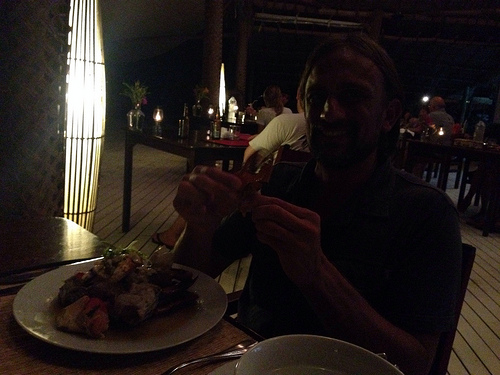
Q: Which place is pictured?
A: It is a restaurant.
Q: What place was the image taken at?
A: It was taken at the restaurant.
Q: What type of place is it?
A: It is a restaurant.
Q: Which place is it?
A: It is a restaurant.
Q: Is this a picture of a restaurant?
A: Yes, it is showing a restaurant.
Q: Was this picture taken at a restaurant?
A: Yes, it was taken in a restaurant.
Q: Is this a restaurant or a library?
A: It is a restaurant.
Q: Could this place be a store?
A: No, it is a restaurant.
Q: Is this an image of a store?
A: No, the picture is showing a restaurant.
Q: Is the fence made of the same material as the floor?
A: Yes, both the fence and the floor are made of wood.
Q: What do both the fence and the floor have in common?
A: The material, both the fence and the floor are wooden.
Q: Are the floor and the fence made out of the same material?
A: Yes, both the floor and the fence are made of wood.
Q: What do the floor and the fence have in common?
A: The material, both the floor and the fence are wooden.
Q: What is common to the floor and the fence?
A: The material, both the floor and the fence are wooden.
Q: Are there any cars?
A: No, there are no cars.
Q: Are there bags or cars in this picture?
A: No, there are no cars or bags.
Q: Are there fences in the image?
A: Yes, there is a fence.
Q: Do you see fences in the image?
A: Yes, there is a fence.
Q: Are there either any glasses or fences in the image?
A: Yes, there is a fence.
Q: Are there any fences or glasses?
A: Yes, there is a fence.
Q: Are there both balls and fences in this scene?
A: No, there is a fence but no balls.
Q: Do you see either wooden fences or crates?
A: Yes, there is a wood fence.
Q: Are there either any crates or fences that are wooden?
A: Yes, the fence is wooden.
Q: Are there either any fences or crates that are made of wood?
A: Yes, the fence is made of wood.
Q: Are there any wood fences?
A: Yes, there is a fence that is made of wood.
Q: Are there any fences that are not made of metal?
A: Yes, there is a fence that is made of wood.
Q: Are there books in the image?
A: No, there are no books.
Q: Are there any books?
A: No, there are no books.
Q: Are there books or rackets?
A: No, there are no books or rackets.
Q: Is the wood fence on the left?
A: Yes, the fence is on the left of the image.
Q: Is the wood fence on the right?
A: No, the fence is on the left of the image.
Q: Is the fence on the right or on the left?
A: The fence is on the left of the image.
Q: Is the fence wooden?
A: Yes, the fence is wooden.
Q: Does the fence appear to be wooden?
A: Yes, the fence is wooden.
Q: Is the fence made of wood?
A: Yes, the fence is made of wood.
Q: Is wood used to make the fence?
A: Yes, the fence is made of wood.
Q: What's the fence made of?
A: The fence is made of wood.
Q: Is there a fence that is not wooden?
A: No, there is a fence but it is wooden.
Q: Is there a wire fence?
A: No, there is a fence but it is made of wood.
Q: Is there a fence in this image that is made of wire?
A: No, there is a fence but it is made of wood.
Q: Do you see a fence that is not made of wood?
A: No, there is a fence but it is made of wood.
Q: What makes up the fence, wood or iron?
A: The fence is made of wood.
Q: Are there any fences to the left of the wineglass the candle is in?
A: Yes, there is a fence to the left of the wine glass.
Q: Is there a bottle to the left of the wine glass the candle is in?
A: No, there is a fence to the left of the wine glass.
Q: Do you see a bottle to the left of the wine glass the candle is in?
A: No, there is a fence to the left of the wine glass.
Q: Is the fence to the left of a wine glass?
A: Yes, the fence is to the left of a wine glass.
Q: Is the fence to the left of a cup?
A: No, the fence is to the left of a wine glass.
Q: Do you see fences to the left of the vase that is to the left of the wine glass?
A: Yes, there is a fence to the left of the vase.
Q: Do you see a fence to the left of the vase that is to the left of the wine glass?
A: Yes, there is a fence to the left of the vase.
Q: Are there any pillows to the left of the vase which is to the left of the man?
A: No, there is a fence to the left of the vase.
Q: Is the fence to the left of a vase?
A: Yes, the fence is to the left of a vase.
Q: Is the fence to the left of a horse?
A: No, the fence is to the left of a vase.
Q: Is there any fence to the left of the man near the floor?
A: Yes, there is a fence to the left of the man.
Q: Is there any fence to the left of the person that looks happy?
A: Yes, there is a fence to the left of the man.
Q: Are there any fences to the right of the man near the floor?
A: No, the fence is to the left of the man.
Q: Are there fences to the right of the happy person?
A: No, the fence is to the left of the man.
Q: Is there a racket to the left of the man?
A: No, there is a fence to the left of the man.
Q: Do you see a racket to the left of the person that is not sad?
A: No, there is a fence to the left of the man.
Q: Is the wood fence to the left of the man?
A: Yes, the fence is to the left of the man.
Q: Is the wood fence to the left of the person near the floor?
A: Yes, the fence is to the left of the man.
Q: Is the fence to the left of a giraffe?
A: No, the fence is to the left of the man.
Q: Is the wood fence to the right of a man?
A: No, the fence is to the left of a man.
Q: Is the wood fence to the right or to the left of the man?
A: The fence is to the left of the man.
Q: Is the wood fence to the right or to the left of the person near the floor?
A: The fence is to the left of the man.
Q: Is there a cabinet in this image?
A: No, there are no cabinets.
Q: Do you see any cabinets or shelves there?
A: No, there are no cabinets or shelves.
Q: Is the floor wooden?
A: Yes, the floor is wooden.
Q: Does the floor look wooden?
A: Yes, the floor is wooden.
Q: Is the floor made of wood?
A: Yes, the floor is made of wood.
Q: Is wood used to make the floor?
A: Yes, the floor is made of wood.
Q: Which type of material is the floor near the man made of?
A: The floor is made of wood.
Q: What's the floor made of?
A: The floor is made of wood.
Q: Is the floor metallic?
A: No, the floor is wooden.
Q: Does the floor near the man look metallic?
A: No, the floor is wooden.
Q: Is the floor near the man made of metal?
A: No, the floor is made of wood.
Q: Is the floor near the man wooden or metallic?
A: The floor is wooden.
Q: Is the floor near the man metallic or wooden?
A: The floor is wooden.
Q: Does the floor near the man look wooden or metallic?
A: The floor is wooden.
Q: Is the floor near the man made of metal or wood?
A: The floor is made of wood.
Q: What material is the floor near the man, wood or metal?
A: The floor is made of wood.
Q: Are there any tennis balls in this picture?
A: No, there are no tennis balls.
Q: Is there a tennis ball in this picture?
A: No, there are no tennis balls.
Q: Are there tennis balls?
A: No, there are no tennis balls.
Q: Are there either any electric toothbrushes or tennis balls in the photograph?
A: No, there are no tennis balls or electric toothbrushes.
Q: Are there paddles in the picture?
A: No, there are no paddles.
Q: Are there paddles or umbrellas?
A: No, there are no paddles or umbrellas.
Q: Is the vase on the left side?
A: Yes, the vase is on the left of the image.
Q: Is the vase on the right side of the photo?
A: No, the vase is on the left of the image.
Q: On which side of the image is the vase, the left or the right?
A: The vase is on the left of the image.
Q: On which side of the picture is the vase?
A: The vase is on the left of the image.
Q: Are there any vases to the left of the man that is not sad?
A: Yes, there is a vase to the left of the man.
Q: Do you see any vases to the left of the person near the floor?
A: Yes, there is a vase to the left of the man.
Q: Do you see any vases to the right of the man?
A: No, the vase is to the left of the man.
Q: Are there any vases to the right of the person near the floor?
A: No, the vase is to the left of the man.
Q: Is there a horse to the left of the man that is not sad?
A: No, there is a vase to the left of the man.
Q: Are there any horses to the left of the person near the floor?
A: No, there is a vase to the left of the man.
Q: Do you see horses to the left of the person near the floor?
A: No, there is a vase to the left of the man.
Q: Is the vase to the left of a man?
A: Yes, the vase is to the left of a man.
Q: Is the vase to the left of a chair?
A: No, the vase is to the left of a man.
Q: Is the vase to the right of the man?
A: No, the vase is to the left of the man.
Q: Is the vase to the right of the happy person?
A: No, the vase is to the left of the man.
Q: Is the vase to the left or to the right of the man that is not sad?
A: The vase is to the left of the man.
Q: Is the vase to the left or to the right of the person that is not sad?
A: The vase is to the left of the man.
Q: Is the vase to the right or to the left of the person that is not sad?
A: The vase is to the left of the man.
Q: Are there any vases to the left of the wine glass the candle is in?
A: Yes, there is a vase to the left of the wineglass.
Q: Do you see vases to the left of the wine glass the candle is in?
A: Yes, there is a vase to the left of the wineglass.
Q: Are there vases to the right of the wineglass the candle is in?
A: No, the vase is to the left of the wine glass.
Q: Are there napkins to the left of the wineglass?
A: No, there is a vase to the left of the wineglass.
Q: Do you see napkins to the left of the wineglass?
A: No, there is a vase to the left of the wineglass.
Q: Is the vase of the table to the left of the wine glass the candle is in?
A: Yes, the vase is to the left of the wine glass.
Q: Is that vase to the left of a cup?
A: No, the vase is to the left of the wine glass.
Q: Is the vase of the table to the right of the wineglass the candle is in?
A: No, the vase is to the left of the wineglass.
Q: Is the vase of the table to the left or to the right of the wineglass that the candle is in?
A: The vase is to the left of the wineglass.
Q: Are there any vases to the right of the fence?
A: Yes, there is a vase to the right of the fence.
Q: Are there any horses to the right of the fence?
A: No, there is a vase to the right of the fence.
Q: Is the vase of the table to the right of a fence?
A: Yes, the vase is to the right of a fence.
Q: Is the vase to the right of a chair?
A: No, the vase is to the right of a fence.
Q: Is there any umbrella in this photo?
A: No, there are no umbrellas.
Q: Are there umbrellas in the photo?
A: No, there are no umbrellas.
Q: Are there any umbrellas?
A: No, there are no umbrellas.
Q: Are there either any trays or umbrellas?
A: No, there are no umbrellas or trays.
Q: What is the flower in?
A: The flower is in the vase.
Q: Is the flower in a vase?
A: Yes, the flower is in a vase.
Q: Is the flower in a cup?
A: No, the flower is in a vase.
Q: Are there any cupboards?
A: No, there are no cupboards.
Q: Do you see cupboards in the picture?
A: No, there are no cupboards.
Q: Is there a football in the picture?
A: No, there are no footballs.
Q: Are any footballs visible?
A: No, there are no footballs.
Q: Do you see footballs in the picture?
A: No, there are no footballs.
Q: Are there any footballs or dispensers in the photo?
A: No, there are no footballs or dispensers.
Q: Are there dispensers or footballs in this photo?
A: No, there are no footballs or dispensers.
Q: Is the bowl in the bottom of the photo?
A: Yes, the bowl is in the bottom of the image.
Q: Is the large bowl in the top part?
A: No, the bowl is in the bottom of the image.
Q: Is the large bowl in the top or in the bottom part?
A: The bowl is in the bottom of the image.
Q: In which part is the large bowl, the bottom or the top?
A: The bowl is in the bottom of the image.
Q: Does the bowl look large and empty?
A: Yes, the bowl is large and empty.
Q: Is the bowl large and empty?
A: Yes, the bowl is large and empty.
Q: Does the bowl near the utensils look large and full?
A: No, the bowl is large but empty.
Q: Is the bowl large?
A: Yes, the bowl is large.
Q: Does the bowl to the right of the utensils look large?
A: Yes, the bowl is large.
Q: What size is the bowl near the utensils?
A: The bowl is large.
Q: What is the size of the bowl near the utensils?
A: The bowl is large.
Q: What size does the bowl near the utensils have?
A: The bowl has large size.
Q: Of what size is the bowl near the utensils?
A: The bowl is large.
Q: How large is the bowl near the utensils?
A: The bowl is large.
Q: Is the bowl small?
A: No, the bowl is large.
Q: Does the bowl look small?
A: No, the bowl is large.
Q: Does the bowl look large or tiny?
A: The bowl is large.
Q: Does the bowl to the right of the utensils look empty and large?
A: Yes, the bowl is empty and large.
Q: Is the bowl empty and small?
A: No, the bowl is empty but large.